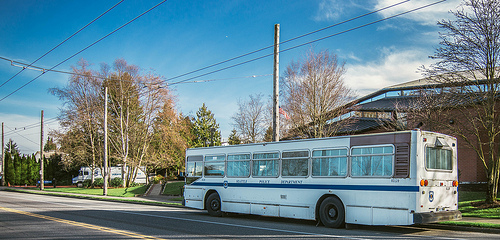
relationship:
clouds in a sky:
[289, 0, 496, 110] [2, 0, 498, 156]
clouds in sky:
[0, 6, 498, 155] [2, 0, 498, 156]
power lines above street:
[4, 0, 445, 140] [4, 189, 483, 238]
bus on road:
[180, 128, 461, 229] [6, 186, 498, 236]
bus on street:
[180, 125, 470, 234] [0, 184, 498, 238]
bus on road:
[180, 125, 470, 234] [6, 188, 384, 238]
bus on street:
[180, 125, 470, 234] [4, 186, 452, 236]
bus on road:
[180, 125, 470, 234] [4, 188, 498, 233]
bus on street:
[180, 125, 470, 234] [4, 189, 483, 238]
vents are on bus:
[391, 137, 414, 180] [180, 125, 470, 234]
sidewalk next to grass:
[144, 175, 165, 198] [167, 177, 180, 195]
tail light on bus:
[418, 176, 430, 192] [180, 125, 470, 234]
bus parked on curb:
[180, 125, 470, 234] [433, 217, 491, 238]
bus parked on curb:
[180, 125, 470, 234] [432, 213, 498, 235]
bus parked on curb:
[180, 125, 470, 234] [427, 218, 497, 236]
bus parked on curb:
[180, 125, 470, 234] [425, 209, 496, 238]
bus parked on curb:
[180, 125, 470, 234] [422, 214, 499, 238]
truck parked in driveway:
[73, 163, 148, 188] [7, 176, 83, 197]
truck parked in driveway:
[73, 160, 148, 188] [5, 176, 79, 196]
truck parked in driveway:
[73, 163, 148, 188] [4, 170, 84, 201]